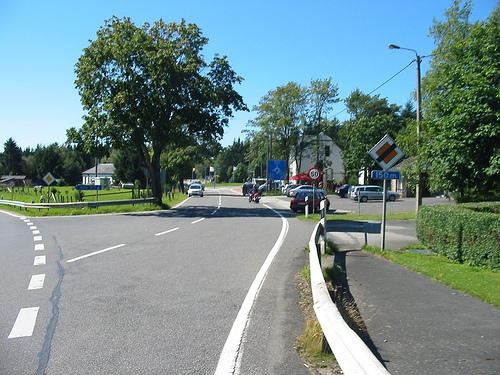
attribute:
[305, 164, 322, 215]
sign — here, red, numbered, square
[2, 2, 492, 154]
sky — blue, clear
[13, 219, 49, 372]
line — white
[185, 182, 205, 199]
car — here, white, silver, parked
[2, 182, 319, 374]
lines — white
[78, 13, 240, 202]
tree — green, tall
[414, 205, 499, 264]
bushes — squared, green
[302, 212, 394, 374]
barricade — steel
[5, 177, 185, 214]
grass — patchy, green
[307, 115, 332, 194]
lamp — tall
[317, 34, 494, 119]
lines — black